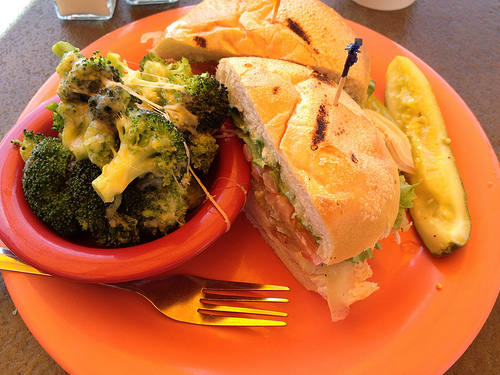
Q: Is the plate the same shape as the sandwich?
A: Yes, both the plate and the sandwich are round.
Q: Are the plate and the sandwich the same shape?
A: Yes, both the plate and the sandwich are round.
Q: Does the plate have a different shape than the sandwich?
A: No, both the plate and the sandwich are round.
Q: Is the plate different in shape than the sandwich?
A: No, both the plate and the sandwich are round.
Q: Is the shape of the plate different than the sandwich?
A: No, both the plate and the sandwich are round.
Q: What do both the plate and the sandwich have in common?
A: The shape, both the plate and the sandwich are round.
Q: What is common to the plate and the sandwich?
A: The shape, both the plate and the sandwich are round.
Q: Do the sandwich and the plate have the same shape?
A: Yes, both the sandwich and the plate are round.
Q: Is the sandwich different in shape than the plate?
A: No, both the sandwich and the plate are round.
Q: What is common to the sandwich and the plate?
A: The shape, both the sandwich and the plate are round.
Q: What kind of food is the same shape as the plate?
A: The sandwich is the same shape as the plate.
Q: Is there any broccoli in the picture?
A: Yes, there is broccoli.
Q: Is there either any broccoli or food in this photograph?
A: Yes, there is broccoli.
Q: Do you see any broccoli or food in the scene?
A: Yes, there is broccoli.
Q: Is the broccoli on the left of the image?
A: Yes, the broccoli is on the left of the image.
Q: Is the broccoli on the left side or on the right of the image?
A: The broccoli is on the left of the image.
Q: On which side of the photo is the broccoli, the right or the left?
A: The broccoli is on the left of the image.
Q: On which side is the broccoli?
A: The broccoli is on the left of the image.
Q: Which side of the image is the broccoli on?
A: The broccoli is on the left of the image.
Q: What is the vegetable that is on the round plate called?
A: The vegetable is broccoli.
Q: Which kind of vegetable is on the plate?
A: The vegetable is broccoli.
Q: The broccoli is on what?
A: The broccoli is on the plate.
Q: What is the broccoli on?
A: The broccoli is on the plate.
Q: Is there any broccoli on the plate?
A: Yes, there is broccoli on the plate.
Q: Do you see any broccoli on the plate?
A: Yes, there is broccoli on the plate.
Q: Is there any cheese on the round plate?
A: No, there is broccoli on the plate.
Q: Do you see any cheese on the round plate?
A: No, there is broccoli on the plate.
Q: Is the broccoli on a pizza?
A: No, the broccoli is on the plate.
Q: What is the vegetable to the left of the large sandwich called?
A: The vegetable is broccoli.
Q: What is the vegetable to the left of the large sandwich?
A: The vegetable is broccoli.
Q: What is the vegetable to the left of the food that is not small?
A: The vegetable is broccoli.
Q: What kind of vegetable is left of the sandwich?
A: The vegetable is broccoli.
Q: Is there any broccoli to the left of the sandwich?
A: Yes, there is broccoli to the left of the sandwich.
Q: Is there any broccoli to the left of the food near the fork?
A: Yes, there is broccoli to the left of the sandwich.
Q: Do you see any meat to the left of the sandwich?
A: No, there is broccoli to the left of the sandwich.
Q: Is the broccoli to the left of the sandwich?
A: Yes, the broccoli is to the left of the sandwich.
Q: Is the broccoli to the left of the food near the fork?
A: Yes, the broccoli is to the left of the sandwich.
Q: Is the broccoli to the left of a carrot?
A: No, the broccoli is to the left of the sandwich.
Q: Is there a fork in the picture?
A: Yes, there is a fork.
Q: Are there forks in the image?
A: Yes, there is a fork.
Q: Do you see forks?
A: Yes, there is a fork.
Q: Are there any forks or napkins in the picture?
A: Yes, there is a fork.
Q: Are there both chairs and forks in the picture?
A: No, there is a fork but no chairs.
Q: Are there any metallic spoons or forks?
A: Yes, there is a metal fork.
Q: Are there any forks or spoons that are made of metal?
A: Yes, the fork is made of metal.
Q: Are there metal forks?
A: Yes, there is a fork that is made of metal.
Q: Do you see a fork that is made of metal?
A: Yes, there is a fork that is made of metal.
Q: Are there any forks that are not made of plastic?
A: Yes, there is a fork that is made of metal.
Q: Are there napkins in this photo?
A: No, there are no napkins.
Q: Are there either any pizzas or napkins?
A: No, there are no napkins or pizzas.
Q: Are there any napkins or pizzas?
A: No, there are no napkins or pizzas.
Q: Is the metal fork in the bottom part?
A: Yes, the fork is in the bottom of the image.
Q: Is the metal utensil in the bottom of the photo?
A: Yes, the fork is in the bottom of the image.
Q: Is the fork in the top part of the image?
A: No, the fork is in the bottom of the image.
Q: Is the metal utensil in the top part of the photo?
A: No, the fork is in the bottom of the image.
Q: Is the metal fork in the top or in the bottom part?
A: The fork is in the bottom of the image.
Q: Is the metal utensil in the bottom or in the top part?
A: The fork is in the bottom of the image.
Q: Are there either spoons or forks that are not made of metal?
A: No, there is a fork but it is made of metal.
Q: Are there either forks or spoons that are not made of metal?
A: No, there is a fork but it is made of metal.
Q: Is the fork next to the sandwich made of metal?
A: Yes, the fork is made of metal.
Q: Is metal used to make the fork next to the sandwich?
A: Yes, the fork is made of metal.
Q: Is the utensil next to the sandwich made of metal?
A: Yes, the fork is made of metal.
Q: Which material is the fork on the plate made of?
A: The fork is made of metal.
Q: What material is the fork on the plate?
A: The fork is made of metal.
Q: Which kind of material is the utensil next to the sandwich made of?
A: The fork is made of metal.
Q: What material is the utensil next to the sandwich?
A: The fork is made of metal.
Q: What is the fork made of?
A: The fork is made of metal.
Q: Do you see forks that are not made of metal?
A: No, there is a fork but it is made of metal.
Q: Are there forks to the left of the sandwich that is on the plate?
A: Yes, there is a fork to the left of the sandwich.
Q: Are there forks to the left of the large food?
A: Yes, there is a fork to the left of the sandwich.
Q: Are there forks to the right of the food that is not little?
A: No, the fork is to the left of the sandwich.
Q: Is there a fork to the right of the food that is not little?
A: No, the fork is to the left of the sandwich.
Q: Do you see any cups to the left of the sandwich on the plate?
A: No, there is a fork to the left of the sandwich.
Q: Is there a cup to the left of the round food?
A: No, there is a fork to the left of the sandwich.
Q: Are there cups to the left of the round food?
A: No, there is a fork to the left of the sandwich.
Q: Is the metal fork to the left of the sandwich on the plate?
A: Yes, the fork is to the left of the sandwich.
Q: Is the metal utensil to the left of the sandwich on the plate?
A: Yes, the fork is to the left of the sandwich.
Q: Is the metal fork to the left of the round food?
A: Yes, the fork is to the left of the sandwich.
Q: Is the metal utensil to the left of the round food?
A: Yes, the fork is to the left of the sandwich.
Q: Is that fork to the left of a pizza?
A: No, the fork is to the left of the sandwich.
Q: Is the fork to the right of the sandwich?
A: No, the fork is to the left of the sandwich.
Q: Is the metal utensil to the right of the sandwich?
A: No, the fork is to the left of the sandwich.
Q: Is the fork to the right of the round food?
A: No, the fork is to the left of the sandwich.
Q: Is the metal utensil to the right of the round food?
A: No, the fork is to the left of the sandwich.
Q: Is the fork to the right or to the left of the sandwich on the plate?
A: The fork is to the left of the sandwich.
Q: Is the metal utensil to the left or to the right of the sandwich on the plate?
A: The fork is to the left of the sandwich.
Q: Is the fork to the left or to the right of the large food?
A: The fork is to the left of the sandwich.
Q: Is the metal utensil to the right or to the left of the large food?
A: The fork is to the left of the sandwich.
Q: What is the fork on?
A: The fork is on the plate.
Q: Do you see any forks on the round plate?
A: Yes, there is a fork on the plate.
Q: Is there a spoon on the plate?
A: No, there is a fork on the plate.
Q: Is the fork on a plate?
A: Yes, the fork is on a plate.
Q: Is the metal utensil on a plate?
A: Yes, the fork is on a plate.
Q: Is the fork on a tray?
A: No, the fork is on a plate.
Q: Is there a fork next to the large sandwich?
A: Yes, there is a fork next to the sandwich.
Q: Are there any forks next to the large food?
A: Yes, there is a fork next to the sandwich.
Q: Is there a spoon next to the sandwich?
A: No, there is a fork next to the sandwich.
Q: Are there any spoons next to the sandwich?
A: No, there is a fork next to the sandwich.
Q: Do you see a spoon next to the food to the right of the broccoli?
A: No, there is a fork next to the sandwich.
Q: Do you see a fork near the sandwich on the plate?
A: Yes, there is a fork near the sandwich.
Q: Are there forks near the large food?
A: Yes, there is a fork near the sandwich.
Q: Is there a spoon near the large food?
A: No, there is a fork near the sandwich.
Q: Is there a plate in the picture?
A: Yes, there is a plate.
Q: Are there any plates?
A: Yes, there is a plate.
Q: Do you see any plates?
A: Yes, there is a plate.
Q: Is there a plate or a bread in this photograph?
A: Yes, there is a plate.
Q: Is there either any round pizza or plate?
A: Yes, there is a round plate.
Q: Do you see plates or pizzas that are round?
A: Yes, the plate is round.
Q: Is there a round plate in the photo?
A: Yes, there is a round plate.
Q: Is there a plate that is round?
A: Yes, there is a plate that is round.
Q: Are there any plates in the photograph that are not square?
A: Yes, there is a round plate.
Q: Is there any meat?
A: No, there is no meat.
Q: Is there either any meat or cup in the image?
A: No, there are no meat or cups.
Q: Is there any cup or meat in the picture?
A: No, there are no meat or cups.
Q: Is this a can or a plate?
A: This is a plate.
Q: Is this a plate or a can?
A: This is a plate.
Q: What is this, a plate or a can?
A: This is a plate.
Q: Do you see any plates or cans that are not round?
A: No, there is a plate but it is round.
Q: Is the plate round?
A: Yes, the plate is round.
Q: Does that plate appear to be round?
A: Yes, the plate is round.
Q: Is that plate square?
A: No, the plate is round.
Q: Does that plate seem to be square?
A: No, the plate is round.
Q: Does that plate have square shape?
A: No, the plate is round.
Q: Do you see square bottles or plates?
A: No, there is a plate but it is round.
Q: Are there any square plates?
A: No, there is a plate but it is round.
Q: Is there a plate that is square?
A: No, there is a plate but it is round.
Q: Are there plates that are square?
A: No, there is a plate but it is round.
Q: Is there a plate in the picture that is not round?
A: No, there is a plate but it is round.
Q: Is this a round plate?
A: Yes, this is a round plate.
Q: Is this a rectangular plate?
A: No, this is a round plate.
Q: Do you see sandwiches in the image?
A: Yes, there is a sandwich.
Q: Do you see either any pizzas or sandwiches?
A: Yes, there is a sandwich.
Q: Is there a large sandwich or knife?
A: Yes, there is a large sandwich.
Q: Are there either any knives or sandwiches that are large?
A: Yes, the sandwich is large.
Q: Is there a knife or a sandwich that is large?
A: Yes, the sandwich is large.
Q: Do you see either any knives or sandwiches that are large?
A: Yes, the sandwich is large.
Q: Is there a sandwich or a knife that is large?
A: Yes, the sandwich is large.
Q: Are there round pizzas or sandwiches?
A: Yes, there is a round sandwich.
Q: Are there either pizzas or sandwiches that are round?
A: Yes, the sandwich is round.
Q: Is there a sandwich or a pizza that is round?
A: Yes, the sandwich is round.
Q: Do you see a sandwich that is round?
A: Yes, there is a round sandwich.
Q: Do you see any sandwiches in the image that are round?
A: Yes, there is a sandwich that is round.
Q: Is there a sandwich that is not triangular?
A: Yes, there is a round sandwich.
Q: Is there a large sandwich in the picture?
A: Yes, there is a large sandwich.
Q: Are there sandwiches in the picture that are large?
A: Yes, there is a sandwich that is large.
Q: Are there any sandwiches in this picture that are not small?
A: Yes, there is a large sandwich.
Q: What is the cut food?
A: The food is a sandwich.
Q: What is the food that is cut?
A: The food is a sandwich.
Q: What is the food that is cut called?
A: The food is a sandwich.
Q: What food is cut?
A: The food is a sandwich.